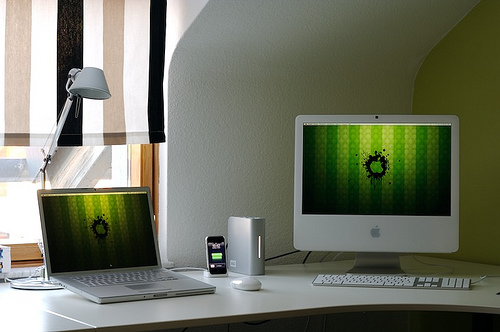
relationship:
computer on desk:
[294, 113, 472, 290] [1, 252, 499, 330]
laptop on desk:
[36, 185, 218, 305] [1, 252, 499, 330]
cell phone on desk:
[203, 234, 230, 279] [1, 252, 499, 330]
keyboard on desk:
[310, 273, 475, 291] [1, 252, 499, 330]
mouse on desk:
[231, 274, 264, 293] [1, 252, 499, 330]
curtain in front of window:
[1, 0, 167, 144] [1, 1, 164, 262]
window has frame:
[1, 1, 164, 262] [1, 143, 161, 267]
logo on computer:
[368, 224, 383, 238] [294, 113, 472, 290]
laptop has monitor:
[36, 185, 218, 305] [40, 190, 162, 275]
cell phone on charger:
[203, 234, 230, 279] [202, 269, 231, 278]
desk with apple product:
[1, 252, 499, 330] [294, 113, 472, 290]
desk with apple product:
[1, 252, 499, 330] [203, 234, 230, 279]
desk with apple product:
[1, 252, 499, 330] [36, 185, 218, 305]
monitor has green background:
[291, 112, 462, 255] [305, 128, 451, 210]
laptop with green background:
[36, 185, 218, 305] [52, 193, 149, 271]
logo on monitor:
[368, 224, 383, 238] [291, 112, 462, 255]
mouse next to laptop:
[231, 274, 264, 293] [36, 185, 218, 305]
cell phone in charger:
[203, 234, 230, 279] [202, 269, 231, 278]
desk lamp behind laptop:
[8, 65, 112, 292] [36, 185, 218, 305]